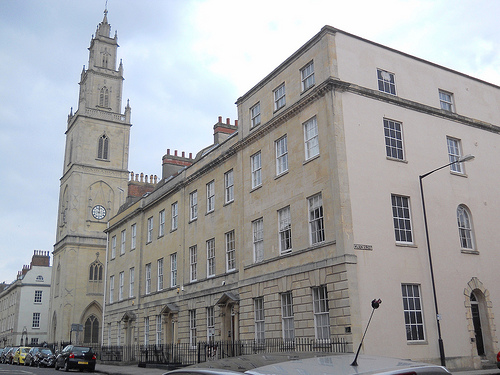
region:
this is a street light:
[441, 149, 478, 171]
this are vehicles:
[1, 341, 93, 369]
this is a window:
[393, 275, 429, 350]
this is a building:
[331, 74, 496, 348]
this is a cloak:
[80, 195, 106, 228]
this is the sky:
[7, 8, 55, 105]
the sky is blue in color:
[7, 7, 65, 87]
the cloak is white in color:
[86, 195, 113, 226]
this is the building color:
[458, 260, 495, 362]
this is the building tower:
[63, 5, 133, 170]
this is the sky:
[2, 24, 53, 226]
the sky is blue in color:
[30, 0, 80, 34]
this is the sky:
[190, 10, 258, 70]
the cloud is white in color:
[208, 11, 253, 70]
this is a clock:
[90, 201, 107, 225]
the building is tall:
[53, 2, 150, 337]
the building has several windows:
[213, 172, 340, 252]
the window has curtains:
[304, 125, 321, 155]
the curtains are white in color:
[304, 129, 321, 156]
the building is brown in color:
[348, 135, 380, 235]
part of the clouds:
[157, 45, 217, 91]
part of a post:
[427, 285, 443, 317]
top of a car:
[306, 345, 332, 364]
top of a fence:
[236, 338, 265, 350]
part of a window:
[278, 217, 290, 253]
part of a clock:
[88, 207, 108, 220]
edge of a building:
[331, 188, 346, 243]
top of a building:
[316, 22, 337, 57]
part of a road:
[5, 359, 23, 371]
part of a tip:
[116, 91, 131, 108]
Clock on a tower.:
[73, 184, 117, 236]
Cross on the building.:
[79, 42, 127, 78]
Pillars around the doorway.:
[196, 287, 254, 350]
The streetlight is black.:
[401, 155, 498, 364]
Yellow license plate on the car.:
[73, 355, 96, 371]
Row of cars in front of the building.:
[0, 337, 120, 373]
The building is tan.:
[146, 222, 431, 339]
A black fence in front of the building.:
[90, 339, 331, 364]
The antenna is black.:
[335, 295, 401, 373]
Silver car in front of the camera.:
[151, 311, 432, 373]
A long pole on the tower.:
[95, 0, 130, 23]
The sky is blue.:
[16, 15, 70, 90]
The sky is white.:
[183, 5, 276, 80]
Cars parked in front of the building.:
[9, 329, 109, 373]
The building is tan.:
[148, 213, 353, 317]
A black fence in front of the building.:
[87, 341, 342, 361]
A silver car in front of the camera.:
[167, 279, 459, 373]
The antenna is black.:
[346, 284, 407, 364]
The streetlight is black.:
[381, 136, 488, 363]